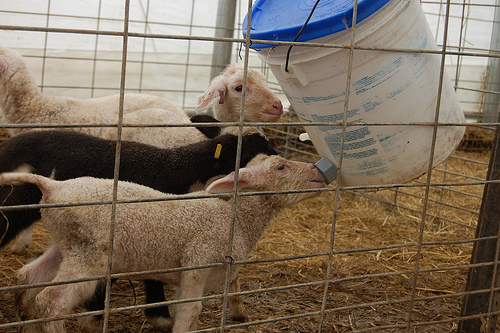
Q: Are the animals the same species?
A: Yes, all the animals are sheep.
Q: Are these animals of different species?
A: No, all the animals are sheep.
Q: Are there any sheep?
A: Yes, there is a sheep.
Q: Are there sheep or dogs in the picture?
A: Yes, there is a sheep.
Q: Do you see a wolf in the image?
A: No, there are no wolves.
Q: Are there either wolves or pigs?
A: No, there are no wolves or pigs.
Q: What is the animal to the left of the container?
A: The animal is a sheep.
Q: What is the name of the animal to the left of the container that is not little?
A: The animal is a sheep.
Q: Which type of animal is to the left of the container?
A: The animal is a sheep.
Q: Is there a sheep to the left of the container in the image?
A: Yes, there is a sheep to the left of the container.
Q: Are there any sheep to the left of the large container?
A: Yes, there is a sheep to the left of the container.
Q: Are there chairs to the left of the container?
A: No, there is a sheep to the left of the container.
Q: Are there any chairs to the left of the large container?
A: No, there is a sheep to the left of the container.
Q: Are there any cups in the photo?
A: No, there are no cups.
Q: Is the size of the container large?
A: Yes, the container is large.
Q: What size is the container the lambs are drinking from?
A: The container is large.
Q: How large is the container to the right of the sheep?
A: The container is large.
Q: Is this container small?
A: No, the container is large.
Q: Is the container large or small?
A: The container is large.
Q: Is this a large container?
A: Yes, this is a large container.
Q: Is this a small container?
A: No, this is a large container.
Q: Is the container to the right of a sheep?
A: Yes, the container is to the right of a sheep.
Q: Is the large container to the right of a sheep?
A: Yes, the container is to the right of a sheep.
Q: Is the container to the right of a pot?
A: No, the container is to the right of a sheep.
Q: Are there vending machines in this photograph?
A: No, there are no vending machines.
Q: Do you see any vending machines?
A: No, there are no vending machines.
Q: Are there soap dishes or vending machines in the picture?
A: No, there are no vending machines or soap dishes.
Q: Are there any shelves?
A: No, there are no shelves.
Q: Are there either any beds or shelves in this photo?
A: No, there are no shelves or beds.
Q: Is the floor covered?
A: Yes, the floor is covered.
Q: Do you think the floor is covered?
A: Yes, the floor is covered.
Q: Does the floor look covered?
A: Yes, the floor is covered.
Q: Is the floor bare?
A: No, the floor is covered.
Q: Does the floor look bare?
A: No, the floor is covered.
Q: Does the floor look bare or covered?
A: The floor is covered.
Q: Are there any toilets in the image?
A: No, there are no toilets.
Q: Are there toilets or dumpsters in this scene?
A: No, there are no toilets or dumpsters.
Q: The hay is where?
A: The hay is on the floor.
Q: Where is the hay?
A: The hay is on the floor.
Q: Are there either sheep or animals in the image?
A: Yes, there is a sheep.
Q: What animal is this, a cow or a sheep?
A: This is a sheep.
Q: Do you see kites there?
A: No, there are no kites.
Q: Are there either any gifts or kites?
A: No, there are no kites or gifts.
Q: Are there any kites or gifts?
A: No, there are no kites or gifts.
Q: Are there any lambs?
A: Yes, there are lambs.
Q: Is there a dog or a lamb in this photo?
A: Yes, there are lambs.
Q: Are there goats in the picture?
A: No, there are no goats.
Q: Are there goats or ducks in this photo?
A: No, there are no goats or ducks.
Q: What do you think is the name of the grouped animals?
A: The animals are lambs.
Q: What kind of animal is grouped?
A: The animal is lambs.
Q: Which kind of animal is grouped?
A: The animal is lambs.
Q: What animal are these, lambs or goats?
A: These are lambs.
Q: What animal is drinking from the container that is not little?
A: The lambs are drinking from the container.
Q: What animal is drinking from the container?
A: The lambs are drinking from the container.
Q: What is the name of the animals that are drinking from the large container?
A: The animals are lambs.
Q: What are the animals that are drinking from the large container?
A: The animals are lambs.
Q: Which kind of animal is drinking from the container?
A: The animals are lambs.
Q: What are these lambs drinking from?
A: The lambs are drinking from the container.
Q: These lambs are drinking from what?
A: The lambs are drinking from the container.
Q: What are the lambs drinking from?
A: The lambs are drinking from the container.